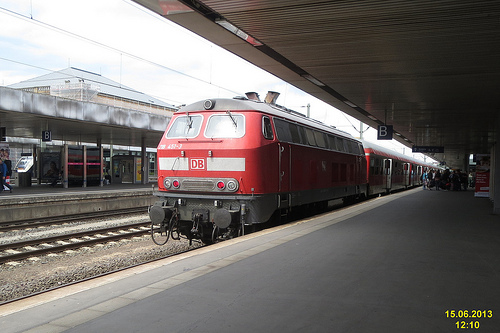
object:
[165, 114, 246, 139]
windshield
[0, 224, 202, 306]
gravel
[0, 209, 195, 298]
ground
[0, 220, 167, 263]
rails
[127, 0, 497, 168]
roof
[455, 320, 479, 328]
time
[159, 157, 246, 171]
line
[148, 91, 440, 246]
train engine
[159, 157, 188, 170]
patch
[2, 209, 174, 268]
tracks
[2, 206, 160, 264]
metal rails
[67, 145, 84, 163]
window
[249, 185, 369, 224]
edge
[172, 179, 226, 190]
red light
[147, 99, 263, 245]
front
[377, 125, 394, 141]
sign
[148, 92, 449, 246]
train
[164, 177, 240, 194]
headlights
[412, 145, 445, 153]
sign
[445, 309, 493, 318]
date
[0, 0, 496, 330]
photograph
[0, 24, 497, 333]
station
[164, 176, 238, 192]
headlight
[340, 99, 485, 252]
terminal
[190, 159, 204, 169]
letter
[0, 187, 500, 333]
platform